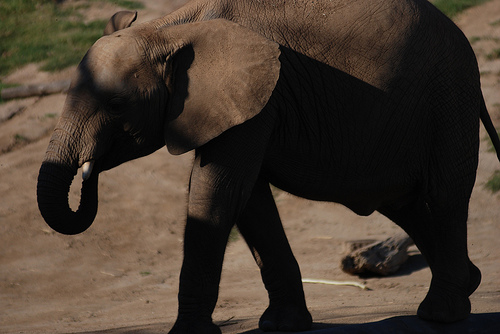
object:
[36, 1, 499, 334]
elephant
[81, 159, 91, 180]
tusk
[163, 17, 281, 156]
ear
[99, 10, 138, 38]
ear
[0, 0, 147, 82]
grass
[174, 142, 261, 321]
legs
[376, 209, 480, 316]
legs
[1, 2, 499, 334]
ground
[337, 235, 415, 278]
rock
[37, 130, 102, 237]
trunk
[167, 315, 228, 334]
feet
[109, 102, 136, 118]
eye